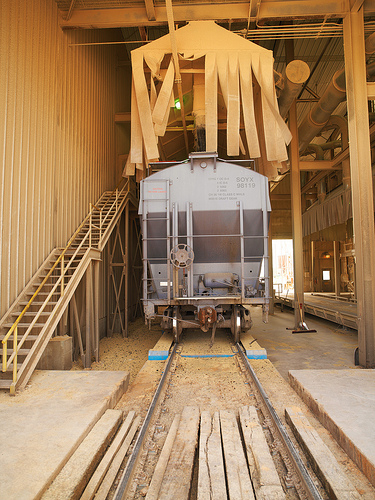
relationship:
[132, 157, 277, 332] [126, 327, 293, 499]
train car on tracks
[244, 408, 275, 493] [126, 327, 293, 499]
wood piece on tracks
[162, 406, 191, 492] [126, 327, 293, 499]
wood piece on tracks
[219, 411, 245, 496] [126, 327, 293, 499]
wood piece on tracks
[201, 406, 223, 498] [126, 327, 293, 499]
wood piece on tracks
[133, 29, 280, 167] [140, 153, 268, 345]
curtain above train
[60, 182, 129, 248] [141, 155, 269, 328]
stairs are beside train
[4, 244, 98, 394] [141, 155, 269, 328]
stairs are beside train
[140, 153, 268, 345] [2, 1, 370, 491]
train inside building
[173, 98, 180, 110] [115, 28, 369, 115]
light on ceiling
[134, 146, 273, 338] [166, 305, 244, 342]
carrier has wheels